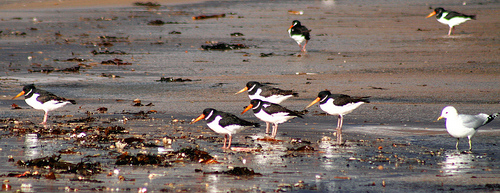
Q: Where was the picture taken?
A: It was taken at the beach.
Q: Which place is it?
A: It is a beach.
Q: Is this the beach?
A: Yes, it is the beach.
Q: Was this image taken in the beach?
A: Yes, it was taken in the beach.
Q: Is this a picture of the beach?
A: Yes, it is showing the beach.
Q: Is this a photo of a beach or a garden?
A: It is showing a beach.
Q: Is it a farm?
A: No, it is a beach.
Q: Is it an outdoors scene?
A: Yes, it is outdoors.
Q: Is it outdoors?
A: Yes, it is outdoors.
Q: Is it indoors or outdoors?
A: It is outdoors.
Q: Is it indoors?
A: No, it is outdoors.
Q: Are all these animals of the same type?
A: Yes, all the animals are birds.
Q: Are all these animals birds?
A: Yes, all the animals are birds.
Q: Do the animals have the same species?
A: Yes, all the animals are birds.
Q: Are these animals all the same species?
A: Yes, all the animals are birds.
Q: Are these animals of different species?
A: No, all the animals are birds.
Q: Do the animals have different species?
A: No, all the animals are birds.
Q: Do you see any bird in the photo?
A: Yes, there is a bird.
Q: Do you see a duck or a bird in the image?
A: Yes, there is a bird.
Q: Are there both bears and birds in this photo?
A: No, there is a bird but no bears.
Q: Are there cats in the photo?
A: No, there are no cats.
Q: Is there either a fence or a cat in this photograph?
A: No, there are no cats or fences.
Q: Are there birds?
A: Yes, there is a bird.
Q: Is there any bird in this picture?
A: Yes, there is a bird.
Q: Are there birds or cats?
A: Yes, there is a bird.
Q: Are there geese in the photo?
A: No, there are no geese.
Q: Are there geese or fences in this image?
A: No, there are no geese or fences.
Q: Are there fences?
A: No, there are no fences.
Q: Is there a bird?
A: Yes, there is a bird.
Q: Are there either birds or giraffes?
A: Yes, there is a bird.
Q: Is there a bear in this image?
A: No, there are no bears.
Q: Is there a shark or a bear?
A: No, there are no bears or sharks.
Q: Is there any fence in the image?
A: No, there are no fences.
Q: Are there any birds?
A: Yes, there is a bird.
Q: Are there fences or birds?
A: Yes, there is a bird.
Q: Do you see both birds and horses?
A: No, there is a bird but no horses.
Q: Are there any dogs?
A: No, there are no dogs.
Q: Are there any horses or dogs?
A: No, there are no dogs or horses.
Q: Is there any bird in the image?
A: Yes, there is a bird.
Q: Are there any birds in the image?
A: Yes, there is a bird.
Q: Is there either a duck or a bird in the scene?
A: Yes, there is a bird.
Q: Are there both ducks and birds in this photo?
A: No, there is a bird but no ducks.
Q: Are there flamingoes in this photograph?
A: No, there are no flamingoes.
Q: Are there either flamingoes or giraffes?
A: No, there are no flamingoes or giraffes.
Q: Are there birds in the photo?
A: Yes, there is a bird.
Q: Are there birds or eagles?
A: Yes, there is a bird.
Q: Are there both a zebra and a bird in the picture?
A: No, there is a bird but no zebras.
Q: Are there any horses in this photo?
A: No, there are no horses.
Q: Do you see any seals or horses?
A: No, there are no horses or seals.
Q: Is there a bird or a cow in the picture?
A: Yes, there is a bird.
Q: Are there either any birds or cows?
A: Yes, there is a bird.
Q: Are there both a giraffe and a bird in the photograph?
A: No, there is a bird but no giraffes.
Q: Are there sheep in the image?
A: No, there are no sheep.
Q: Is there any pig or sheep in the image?
A: No, there are no sheep or pigs.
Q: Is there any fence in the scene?
A: No, there are no fences.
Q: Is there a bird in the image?
A: Yes, there is a bird.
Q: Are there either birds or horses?
A: Yes, there is a bird.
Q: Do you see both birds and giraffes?
A: No, there is a bird but no giraffes.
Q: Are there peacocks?
A: No, there are no peacocks.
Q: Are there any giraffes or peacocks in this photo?
A: No, there are no peacocks or giraffes.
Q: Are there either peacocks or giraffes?
A: No, there are no peacocks or giraffes.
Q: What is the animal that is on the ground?
A: The animal is a bird.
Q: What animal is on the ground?
A: The animal is a bird.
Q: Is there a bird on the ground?
A: Yes, there is a bird on the ground.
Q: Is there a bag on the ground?
A: No, there is a bird on the ground.